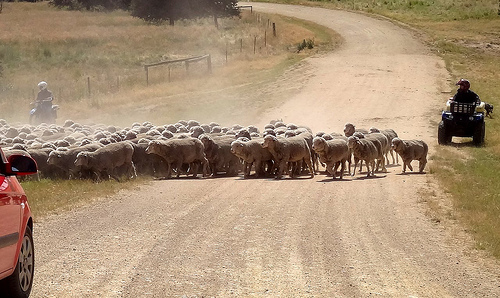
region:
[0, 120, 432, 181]
a herd of sheep is moving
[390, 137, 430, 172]
a sheep is at the end of the herd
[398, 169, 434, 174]
a shadow is on the ground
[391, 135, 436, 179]
the sheep is casting a shadow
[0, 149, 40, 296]
a car is on the road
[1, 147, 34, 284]
the car is red in color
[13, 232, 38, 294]
the tire is made of rubber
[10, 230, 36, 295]
the tire is black in color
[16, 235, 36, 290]
the tire has a hubcap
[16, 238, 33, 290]
the hubcap is grey in color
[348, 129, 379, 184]
Small brown sheep in field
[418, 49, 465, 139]
Man on an atv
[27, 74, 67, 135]
Man on an atv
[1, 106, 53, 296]
Red vehicle parked on dirt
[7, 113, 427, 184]
Large heard of sheep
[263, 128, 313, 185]
Small brown sheep in field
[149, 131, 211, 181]
Small brown sheep in field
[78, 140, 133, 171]
Small brown sheep in field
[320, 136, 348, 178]
Small brown sheep in field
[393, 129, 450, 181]
Small brown sheep in dirt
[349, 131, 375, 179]
Small brown sheep in dirt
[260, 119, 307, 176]
Small brown sheep in dirt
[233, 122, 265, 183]
Small brown sheep in dirt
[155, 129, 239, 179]
Small brown sheep in dirt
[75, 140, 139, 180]
Small brown sheep in dirt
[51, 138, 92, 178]
Small brown sheep in dirt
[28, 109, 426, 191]
Heard of brown sheep in dirt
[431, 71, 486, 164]
Man on an atv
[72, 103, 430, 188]
herd of sheep crossing road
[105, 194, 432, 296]
brown dirt road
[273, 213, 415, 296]
vehicle tracks on brown dirt road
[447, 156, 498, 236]
grass growing beside road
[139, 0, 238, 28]
trees with green leaves beside road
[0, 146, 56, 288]
red car stopped in road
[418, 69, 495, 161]
person on black four wheeler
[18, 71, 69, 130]
person riding motorcycle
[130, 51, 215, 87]
brown wooden fence posts beside road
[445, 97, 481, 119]
black plastic basket on front of four wheeler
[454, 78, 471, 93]
The red helmet on the guy's head.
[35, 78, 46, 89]
The white helmet on the guy's head.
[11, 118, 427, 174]
The sheep in the middle of the road.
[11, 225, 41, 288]
The front wheel of the car.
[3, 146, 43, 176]
The side view mirror of the car.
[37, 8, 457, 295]
The dirt road the sheep are on.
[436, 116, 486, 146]
The tires on the 4-wheeler on the right.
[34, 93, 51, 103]
The black shirt the rider on the left is wearing.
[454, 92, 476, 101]
The black shirt the rider on the right is wearing.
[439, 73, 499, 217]
The grass area where the 4 wheeler is positioned.